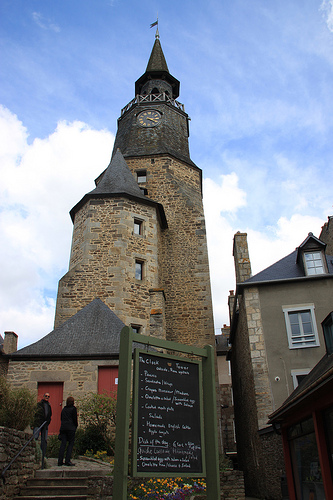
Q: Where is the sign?
A: Foreground.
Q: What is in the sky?
A: Clouds.